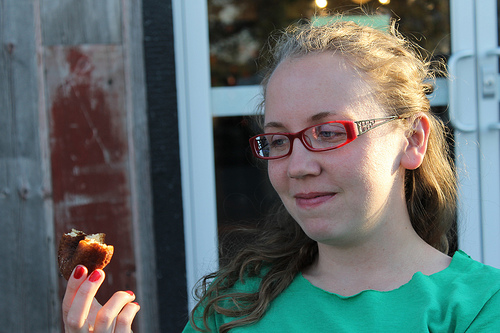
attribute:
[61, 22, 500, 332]
girl — smiling, blonde, smirking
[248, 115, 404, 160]
glasses — red framed, red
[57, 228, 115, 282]
donut — half, pastry, eaten, bitten, food, piece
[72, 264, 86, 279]
fingernail — polished, red, polised, bright red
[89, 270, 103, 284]
fingernail — polished, red, bright red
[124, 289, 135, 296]
fingernail — polished, red, bright red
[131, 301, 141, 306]
fingernail — polished, red, bright red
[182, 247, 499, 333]
shirt — green, cotton, aqua, collarless, light blue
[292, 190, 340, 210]
lips — red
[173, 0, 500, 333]
door — glass, metal, large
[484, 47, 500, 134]
handle — chrome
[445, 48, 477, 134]
handle — chrome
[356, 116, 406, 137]
side — metal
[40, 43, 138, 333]
paint — faded, red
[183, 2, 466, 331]
hair — brown